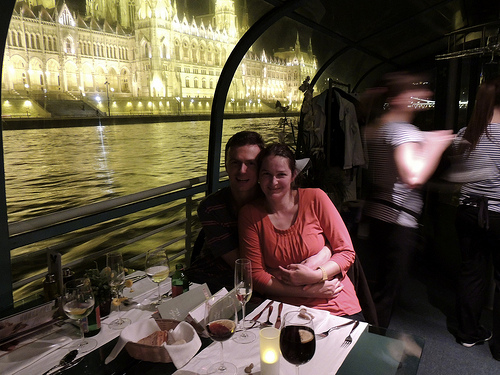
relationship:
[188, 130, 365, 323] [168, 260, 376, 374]
couple having dinner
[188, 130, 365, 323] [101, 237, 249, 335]
couple having dinner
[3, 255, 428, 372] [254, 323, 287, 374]
table has candle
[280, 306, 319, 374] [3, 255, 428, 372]
wine on table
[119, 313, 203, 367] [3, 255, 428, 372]
bread on table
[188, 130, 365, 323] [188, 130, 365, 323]
couple holding couple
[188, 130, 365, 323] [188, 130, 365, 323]
couple in couple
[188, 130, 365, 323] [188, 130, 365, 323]
couple with couple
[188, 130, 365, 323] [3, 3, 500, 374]
couple on cruise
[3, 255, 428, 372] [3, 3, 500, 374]
dinner on cruise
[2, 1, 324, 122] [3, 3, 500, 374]
building at night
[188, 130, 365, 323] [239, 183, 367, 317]
couple wearing shirt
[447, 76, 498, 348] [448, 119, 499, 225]
woman wearing shirt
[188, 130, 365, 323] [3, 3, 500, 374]
couple in photo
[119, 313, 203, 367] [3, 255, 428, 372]
basket on table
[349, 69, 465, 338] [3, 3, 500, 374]
lady in photo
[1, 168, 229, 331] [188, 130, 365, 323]
railing for couple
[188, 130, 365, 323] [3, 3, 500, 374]
couple at restaraunt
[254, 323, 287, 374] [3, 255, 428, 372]
candle on table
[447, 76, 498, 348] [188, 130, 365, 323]
woman behind couple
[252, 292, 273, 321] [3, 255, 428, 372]
knife on table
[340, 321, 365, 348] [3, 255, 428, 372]
fork on table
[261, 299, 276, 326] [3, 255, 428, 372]
spoon on table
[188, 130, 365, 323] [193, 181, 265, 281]
couple wearing shirt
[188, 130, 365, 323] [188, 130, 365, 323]
couple hugging couple